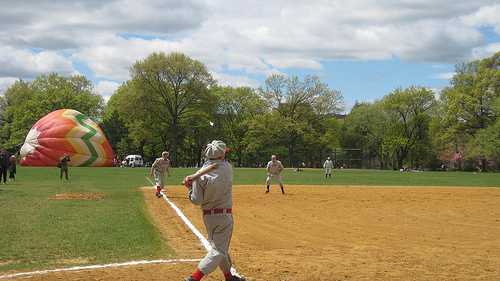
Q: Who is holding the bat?
A: The player.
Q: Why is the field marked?
A: Its a playing field.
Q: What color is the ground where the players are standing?
A: Brown.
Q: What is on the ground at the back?
A: A hot air balloon.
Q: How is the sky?
A: Cloudy.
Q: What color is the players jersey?
A: Grey.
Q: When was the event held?
A: Daytime.